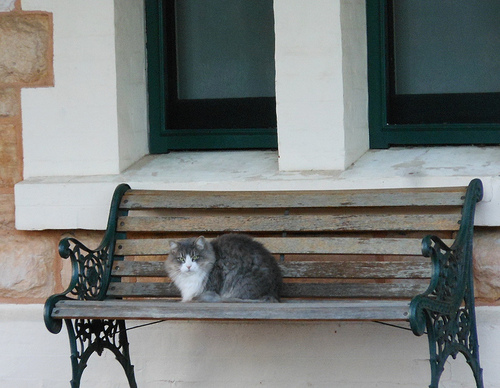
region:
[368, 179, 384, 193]
part of a wall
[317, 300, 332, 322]
part of a bench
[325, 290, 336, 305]
edge of a bench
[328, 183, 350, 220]
part of a wall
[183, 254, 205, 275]
face of a cat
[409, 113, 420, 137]
part of a window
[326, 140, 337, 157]
side of a wall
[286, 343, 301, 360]
part of a wall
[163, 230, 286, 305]
a cat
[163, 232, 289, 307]
a cat on a bench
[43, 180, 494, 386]
a bench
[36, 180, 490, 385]
a wooden bench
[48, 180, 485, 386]
the bench has metal sides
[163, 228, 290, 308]
the cat is sitting on a bench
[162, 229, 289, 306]
the cat is grey and white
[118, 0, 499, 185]
a window in a building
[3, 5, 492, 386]
a building behind the bench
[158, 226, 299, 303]
the cat is looking at the camera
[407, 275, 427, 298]
part of a bench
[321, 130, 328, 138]
part of a wall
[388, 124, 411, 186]
part of a window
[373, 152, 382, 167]
edge of a window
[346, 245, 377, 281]
part of a bench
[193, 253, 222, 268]
head of a cat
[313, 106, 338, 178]
part of a wall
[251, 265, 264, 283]
head of a cat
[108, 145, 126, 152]
part of a wall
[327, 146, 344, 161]
side of a wall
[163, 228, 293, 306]
A big fury gray and white cat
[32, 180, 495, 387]
A bench with a fury cat on it.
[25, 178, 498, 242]
The back of a wooden bench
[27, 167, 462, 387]
A wooden bench with a cat on it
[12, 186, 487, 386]
A wood and iron bench under a window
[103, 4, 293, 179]
A window on a building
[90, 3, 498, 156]
A set of windows on a building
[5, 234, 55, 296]
A piece of block from a building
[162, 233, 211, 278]
The face of a gray and white cat on a bench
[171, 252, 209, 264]
The eyes of a cat on a bench under windows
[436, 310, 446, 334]
side of a bench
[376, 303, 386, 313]
edge of a bench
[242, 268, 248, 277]
back of a cat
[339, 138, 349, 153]
part of a wall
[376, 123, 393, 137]
part of a window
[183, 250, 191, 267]
head of a cat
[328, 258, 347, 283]
back of a bench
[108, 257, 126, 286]
side of a bench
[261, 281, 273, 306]
tail of a cat